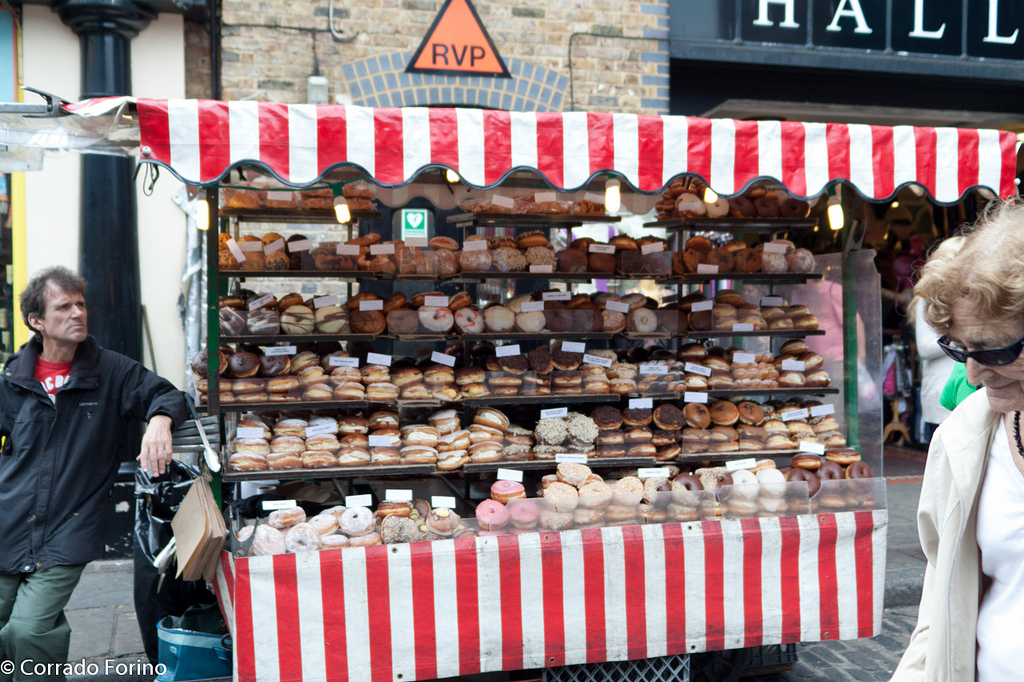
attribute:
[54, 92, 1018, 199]
cart roof — red, white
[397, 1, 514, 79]
triangle sign — black and orange, in the wall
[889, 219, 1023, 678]
people — enjoying the outdoors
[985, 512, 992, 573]
shirt — white